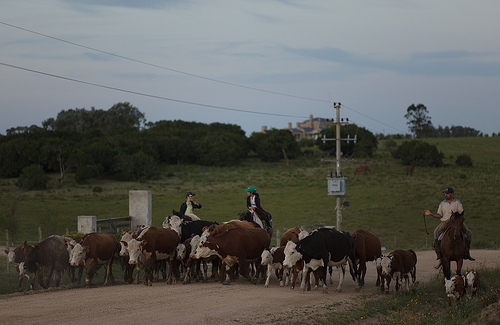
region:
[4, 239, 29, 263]
a brown and white cow walking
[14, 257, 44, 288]
a brown and white cow walking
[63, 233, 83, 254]
a brown and white cow walking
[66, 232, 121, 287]
a brown and white cow walking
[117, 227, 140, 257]
a brown and white cow walking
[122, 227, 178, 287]
a brown and white cow walking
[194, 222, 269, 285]
a brown and white cow walking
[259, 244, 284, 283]
a brown and white cow walking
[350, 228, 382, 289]
a brown and white cow walking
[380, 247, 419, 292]
a brown and white cow walking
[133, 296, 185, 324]
the dirt of the road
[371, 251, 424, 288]
a small cow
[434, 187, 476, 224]
a man on the horse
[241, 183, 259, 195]
a green hat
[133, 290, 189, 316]
dirt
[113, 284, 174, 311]
the dirt is brown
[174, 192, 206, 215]
a person on a horse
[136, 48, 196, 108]
electrical lines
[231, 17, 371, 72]
clouds in the sky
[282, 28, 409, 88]
the sky is cloudy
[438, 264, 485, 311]
two small brown and white calves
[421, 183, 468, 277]
man riding a horse wearing a baseball cap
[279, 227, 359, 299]
large black cow with a white face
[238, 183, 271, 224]
person on horseback wearing a green hat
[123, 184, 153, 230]
gray cement column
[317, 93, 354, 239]
utility pole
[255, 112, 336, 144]
large home on the hill top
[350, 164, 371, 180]
horse grazing in the distance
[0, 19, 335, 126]
power lines overhead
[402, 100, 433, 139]
tree on the hill top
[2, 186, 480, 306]
Three people herding cattle.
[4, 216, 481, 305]
All of the cows have white patches on them.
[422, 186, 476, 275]
The man is riding a horse.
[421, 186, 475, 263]
The man is holding something in his right hand.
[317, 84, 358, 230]
A utility pole with a large box attached.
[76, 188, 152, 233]
A gate with a cement post on both sides.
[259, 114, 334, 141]
A large building in the distance.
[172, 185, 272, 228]
Two women talking while riding horses.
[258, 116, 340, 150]
House in the distance.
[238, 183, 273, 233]
Person on a horse.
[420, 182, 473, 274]
Man riding a horse.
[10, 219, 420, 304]
Herd of cattle on a road.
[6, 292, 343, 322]
A dirt road in the country.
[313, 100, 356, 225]
An electric pole in the country.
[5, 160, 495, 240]
A green pasture in the country.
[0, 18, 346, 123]
Electric lines connected to a pole.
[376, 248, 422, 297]
Brown and white cow on a road.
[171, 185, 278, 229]
Two people riding horses.